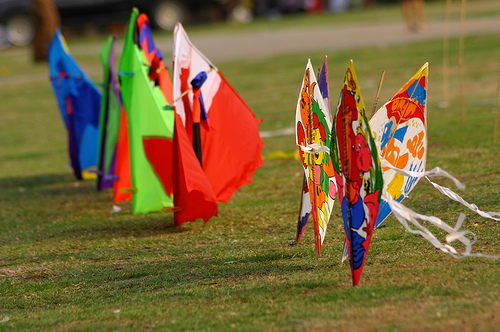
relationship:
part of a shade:
[0, 261, 163, 317] [0, 246, 339, 318]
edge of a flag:
[172, 22, 183, 227] [171, 19, 267, 228]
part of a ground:
[0, 253, 500, 331] [0, 1, 499, 331]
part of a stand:
[0, 0, 104, 50] [3, 0, 464, 50]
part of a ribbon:
[437, 166, 466, 191] [378, 158, 464, 191]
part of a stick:
[34, 26, 60, 63] [34, 1, 61, 62]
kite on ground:
[330, 60, 385, 287] [0, 1, 499, 331]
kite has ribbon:
[294, 59, 338, 252] [378, 158, 464, 191]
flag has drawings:
[171, 19, 267, 228] [178, 35, 207, 167]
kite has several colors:
[330, 60, 385, 287] [331, 61, 382, 284]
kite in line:
[330, 60, 385, 287] [47, 9, 431, 286]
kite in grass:
[330, 60, 385, 287] [1, 84, 499, 331]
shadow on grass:
[0, 211, 185, 246] [1, 84, 499, 331]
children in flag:
[178, 35, 207, 167] [171, 19, 267, 228]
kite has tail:
[47, 28, 102, 180] [262, 151, 299, 162]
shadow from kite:
[0, 211, 185, 246] [171, 19, 267, 228]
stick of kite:
[349, 61, 357, 293] [330, 60, 385, 287]